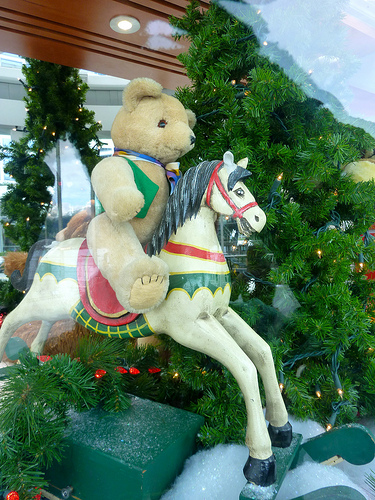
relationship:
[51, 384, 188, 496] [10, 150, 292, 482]
box under horse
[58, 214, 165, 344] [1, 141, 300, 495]
saddle on horse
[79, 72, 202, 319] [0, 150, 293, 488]
bear on rocking horse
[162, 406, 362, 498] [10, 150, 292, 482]
snow under horse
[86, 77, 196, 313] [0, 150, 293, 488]
teddy bear on rocking horse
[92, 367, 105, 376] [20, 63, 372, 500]
light on tree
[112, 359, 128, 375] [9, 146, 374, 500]
light on tree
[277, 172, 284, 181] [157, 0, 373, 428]
light on christmas tree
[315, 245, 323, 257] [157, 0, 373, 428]
light on christmas tree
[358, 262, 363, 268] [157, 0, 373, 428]
light on christmas tree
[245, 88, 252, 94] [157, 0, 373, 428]
light on christmas tree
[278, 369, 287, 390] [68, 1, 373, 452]
light on christmas tree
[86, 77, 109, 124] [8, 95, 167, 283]
sunlight passes through window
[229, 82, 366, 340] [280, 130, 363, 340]
tree with lights